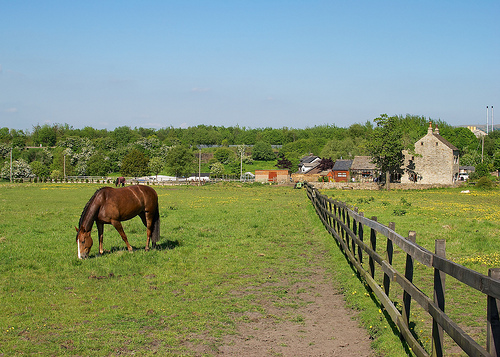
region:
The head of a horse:
[75, 228, 90, 258]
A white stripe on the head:
[75, 239, 80, 257]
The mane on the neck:
[83, 205, 88, 212]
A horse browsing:
[114, 177, 124, 185]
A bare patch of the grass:
[320, 320, 347, 346]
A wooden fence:
[369, 220, 374, 252]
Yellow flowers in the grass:
[480, 258, 497, 264]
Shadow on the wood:
[407, 260, 412, 275]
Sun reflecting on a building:
[428, 154, 445, 181]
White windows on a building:
[338, 171, 348, 177]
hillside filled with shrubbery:
[3, 111, 498, 181]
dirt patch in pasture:
[188, 251, 378, 355]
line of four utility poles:
[7, 146, 244, 181]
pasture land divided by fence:
[4, 179, 499, 353]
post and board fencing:
[300, 178, 499, 355]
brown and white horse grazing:
[72, 182, 162, 262]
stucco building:
[400, 120, 460, 186]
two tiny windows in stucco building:
[418, 138, 440, 147]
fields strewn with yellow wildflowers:
[2, 179, 497, 355]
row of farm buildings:
[133, 151, 385, 183]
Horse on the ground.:
[54, 154, 199, 270]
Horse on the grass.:
[54, 160, 299, 310]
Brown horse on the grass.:
[64, 172, 165, 262]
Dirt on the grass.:
[205, 239, 412, 350]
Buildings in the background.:
[240, 137, 432, 198]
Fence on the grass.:
[315, 166, 420, 317]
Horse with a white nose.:
[42, 152, 147, 301]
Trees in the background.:
[128, 124, 272, 190]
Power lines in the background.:
[221, 128, 288, 191]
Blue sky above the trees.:
[287, 54, 486, 161]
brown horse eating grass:
[45, 173, 178, 302]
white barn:
[411, 124, 457, 188]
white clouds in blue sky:
[11, 14, 65, 50]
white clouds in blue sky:
[33, 53, 87, 88]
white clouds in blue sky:
[93, 27, 146, 59]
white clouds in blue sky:
[144, 14, 202, 58]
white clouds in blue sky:
[228, 0, 266, 40]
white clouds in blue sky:
[228, 55, 276, 84]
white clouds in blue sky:
[285, 73, 323, 109]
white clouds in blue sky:
[304, 20, 374, 79]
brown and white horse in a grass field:
[61, 161, 169, 262]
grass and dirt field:
[30, 270, 334, 348]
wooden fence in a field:
[290, 155, 490, 346]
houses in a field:
[301, 120, 466, 188]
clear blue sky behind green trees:
[107, 21, 240, 173]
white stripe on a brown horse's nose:
[65, 220, 101, 266]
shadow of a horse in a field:
[100, 235, 185, 257]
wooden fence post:
[420, 225, 455, 352]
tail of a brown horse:
[148, 183, 163, 249]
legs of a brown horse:
[94, 212, 161, 254]